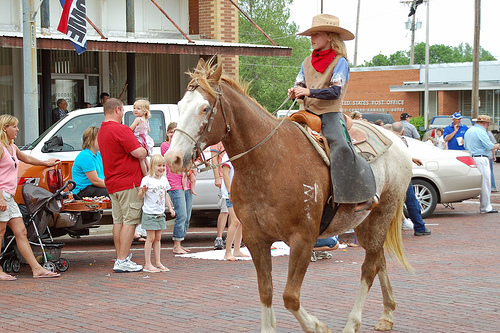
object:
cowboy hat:
[294, 13, 356, 41]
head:
[309, 30, 334, 51]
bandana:
[310, 49, 338, 74]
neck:
[318, 41, 332, 51]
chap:
[321, 112, 378, 203]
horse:
[164, 56, 413, 333]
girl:
[287, 13, 377, 213]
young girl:
[136, 154, 176, 273]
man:
[96, 97, 148, 273]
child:
[129, 99, 155, 177]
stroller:
[0, 179, 77, 274]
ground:
[0, 193, 500, 333]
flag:
[55, 1, 87, 55]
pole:
[21, 0, 41, 147]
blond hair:
[387, 206, 418, 277]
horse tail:
[384, 199, 416, 278]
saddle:
[287, 110, 368, 147]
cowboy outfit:
[292, 53, 377, 203]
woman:
[0, 113, 62, 281]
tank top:
[0, 142, 19, 197]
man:
[463, 113, 499, 214]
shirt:
[462, 124, 495, 157]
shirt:
[220, 152, 235, 198]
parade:
[162, 11, 420, 332]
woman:
[71, 126, 107, 200]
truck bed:
[62, 196, 112, 212]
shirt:
[97, 120, 144, 195]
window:
[123, 110, 166, 148]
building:
[1, 0, 291, 147]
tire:
[402, 178, 438, 218]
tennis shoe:
[111, 258, 145, 272]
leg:
[241, 227, 276, 333]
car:
[402, 136, 482, 219]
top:
[71, 148, 104, 195]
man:
[443, 112, 470, 150]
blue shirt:
[443, 122, 470, 151]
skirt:
[140, 212, 168, 230]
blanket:
[174, 241, 291, 261]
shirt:
[139, 174, 172, 215]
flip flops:
[142, 267, 160, 274]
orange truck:
[0, 159, 112, 245]